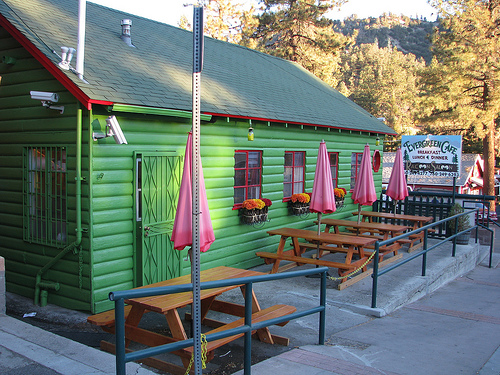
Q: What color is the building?
A: Green.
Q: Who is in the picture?
A: There are no people in the picture.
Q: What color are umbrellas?
A: Pink.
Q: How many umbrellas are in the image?
A: Four.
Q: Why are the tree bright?
A: The sun is shining on them.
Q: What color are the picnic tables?
A: Brown.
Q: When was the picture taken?
A: During the day.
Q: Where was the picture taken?
A: At the Evergreen Cafe.